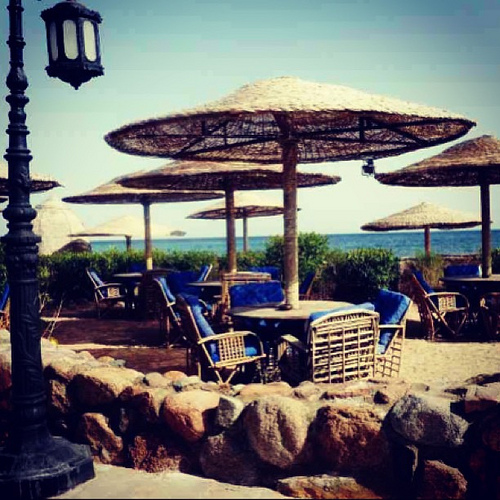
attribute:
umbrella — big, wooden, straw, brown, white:
[113, 73, 469, 183]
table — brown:
[231, 293, 373, 347]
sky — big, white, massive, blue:
[0, 1, 496, 216]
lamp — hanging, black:
[37, 5, 113, 89]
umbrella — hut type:
[373, 133, 498, 193]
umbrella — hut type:
[119, 160, 341, 279]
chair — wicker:
[176, 293, 272, 389]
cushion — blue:
[195, 306, 225, 354]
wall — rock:
[71, 365, 488, 491]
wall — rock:
[55, 350, 495, 491]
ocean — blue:
[337, 230, 489, 259]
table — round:
[225, 295, 374, 324]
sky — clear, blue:
[108, 4, 498, 56]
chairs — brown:
[173, 294, 278, 384]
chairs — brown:
[271, 302, 380, 386]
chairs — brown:
[369, 285, 406, 378]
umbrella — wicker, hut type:
[102, 72, 480, 167]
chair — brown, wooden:
[175, 293, 268, 382]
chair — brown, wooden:
[281, 300, 382, 383]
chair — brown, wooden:
[369, 285, 415, 379]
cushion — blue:
[183, 293, 256, 359]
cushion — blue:
[308, 300, 376, 320]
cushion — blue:
[372, 286, 410, 345]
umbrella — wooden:
[376, 135, 498, 188]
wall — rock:
[2, 327, 499, 498]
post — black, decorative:
[0, 0, 96, 499]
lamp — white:
[39, 0, 105, 90]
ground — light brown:
[42, 303, 498, 386]